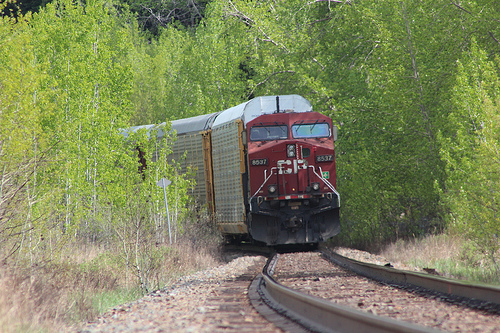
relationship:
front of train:
[248, 106, 343, 255] [115, 87, 350, 258]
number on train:
[315, 154, 332, 162] [115, 87, 350, 258]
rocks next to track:
[80, 255, 282, 331] [201, 242, 498, 329]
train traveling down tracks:
[115, 87, 350, 258] [260, 239, 496, 331]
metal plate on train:
[246, 190, 348, 247] [115, 87, 350, 258]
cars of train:
[151, 89, 343, 248] [109, 93, 339, 247]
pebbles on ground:
[76, 254, 261, 331] [81, 247, 494, 329]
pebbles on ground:
[76, 254, 261, 331] [120, 261, 224, 326]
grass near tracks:
[6, 234, 209, 327] [260, 239, 496, 331]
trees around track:
[1, 5, 498, 252] [244, 230, 499, 329]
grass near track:
[412, 250, 497, 284] [223, 257, 498, 331]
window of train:
[247, 124, 287, 141] [109, 93, 339, 247]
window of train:
[290, 122, 332, 138] [109, 93, 339, 247]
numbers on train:
[250, 158, 270, 167] [109, 93, 339, 247]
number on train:
[315, 154, 332, 162] [109, 93, 339, 247]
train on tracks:
[115, 87, 350, 258] [266, 254, 472, 327]